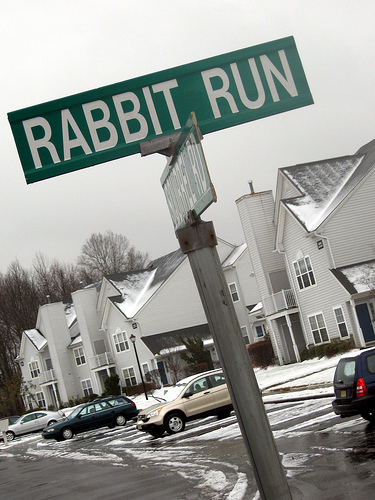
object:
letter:
[20, 112, 62, 172]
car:
[42, 395, 139, 441]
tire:
[62, 427, 72, 437]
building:
[273, 139, 374, 368]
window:
[288, 253, 318, 293]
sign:
[5, 35, 316, 186]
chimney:
[248, 181, 256, 193]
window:
[307, 311, 332, 346]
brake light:
[353, 377, 366, 400]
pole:
[134, 343, 151, 402]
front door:
[353, 301, 374, 348]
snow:
[1, 434, 354, 500]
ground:
[3, 346, 374, 498]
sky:
[0, 1, 374, 277]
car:
[135, 367, 234, 440]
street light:
[125, 333, 152, 403]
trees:
[75, 229, 152, 285]